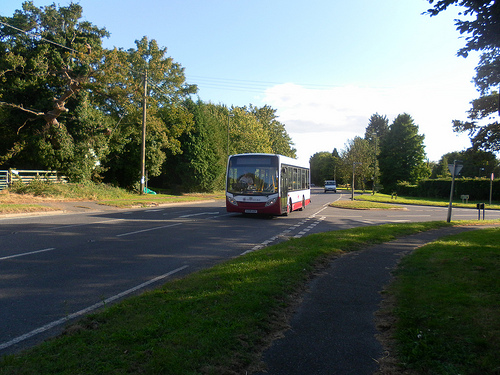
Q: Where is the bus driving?
A: Down the road.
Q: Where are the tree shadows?
A: On the ground.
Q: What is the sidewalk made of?
A: Gray cement.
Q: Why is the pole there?
A: To hold telephone wires.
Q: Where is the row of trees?
A: Next to the road.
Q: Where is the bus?
A: On the street.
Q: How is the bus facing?
A: Toward the viewer.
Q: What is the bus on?
A: A road.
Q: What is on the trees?
A: Leaves.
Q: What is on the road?
A: A bus.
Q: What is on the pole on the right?
A: A sign.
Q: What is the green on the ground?
A: Grass.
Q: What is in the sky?
A: Clouds.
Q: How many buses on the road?
A: One.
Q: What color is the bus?
A: White and red.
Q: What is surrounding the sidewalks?
A: Grass.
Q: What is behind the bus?
A: A truck.